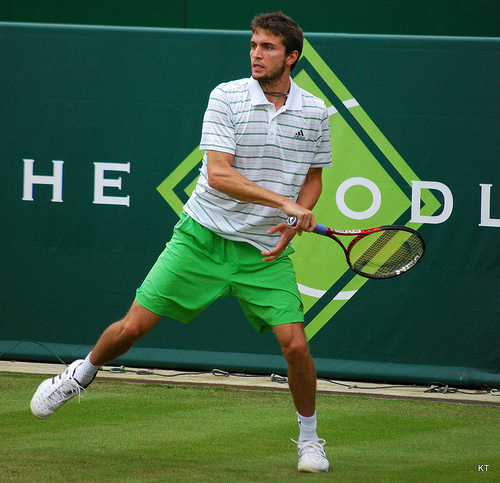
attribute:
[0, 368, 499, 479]
grass — green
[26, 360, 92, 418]
shoe — white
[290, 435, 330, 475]
shoe — white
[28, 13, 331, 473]
man — playing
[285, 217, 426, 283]
racket — red, black, blue, black,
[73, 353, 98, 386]
sock — white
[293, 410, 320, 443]
sock — white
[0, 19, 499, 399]
wall — green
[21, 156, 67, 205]
letter — white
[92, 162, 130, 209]
letter — white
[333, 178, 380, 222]
letter — white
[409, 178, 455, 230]
letter — white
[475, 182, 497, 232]
letter — white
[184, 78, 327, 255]
shirt — green, white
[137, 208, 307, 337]
shorts — green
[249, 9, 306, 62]
hair — brown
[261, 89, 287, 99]
necklace — cord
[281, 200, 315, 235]
hand — folded